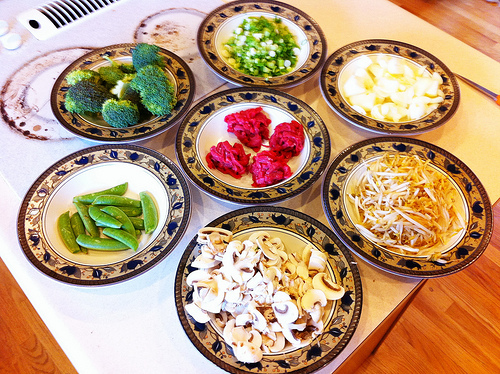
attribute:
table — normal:
[1, 7, 499, 372]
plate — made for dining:
[178, 193, 375, 370]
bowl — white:
[9, 138, 196, 288]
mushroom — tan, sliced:
[310, 266, 345, 301]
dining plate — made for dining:
[199, 7, 321, 84]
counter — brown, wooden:
[368, 299, 492, 372]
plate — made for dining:
[16, 147, 187, 287]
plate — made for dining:
[170, 199, 361, 370]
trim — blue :
[331, 281, 363, 351]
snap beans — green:
[138, 188, 158, 233]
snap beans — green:
[102, 225, 139, 252]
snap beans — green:
[73, 232, 130, 249]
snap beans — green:
[56, 208, 81, 253]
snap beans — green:
[91, 192, 141, 207]